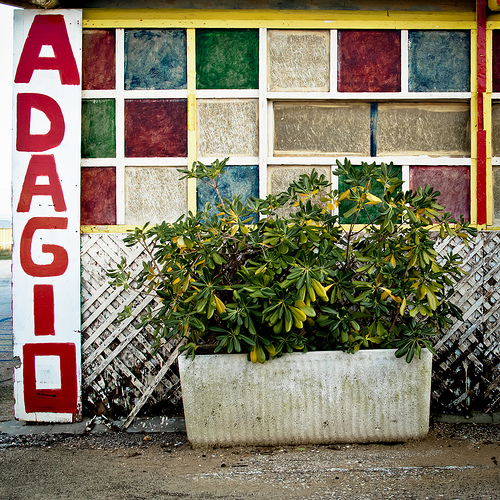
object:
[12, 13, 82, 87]
letter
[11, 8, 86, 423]
sign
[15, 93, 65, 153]
letter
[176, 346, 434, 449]
pot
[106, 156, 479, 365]
plant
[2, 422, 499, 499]
ground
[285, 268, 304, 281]
leaf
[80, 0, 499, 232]
wall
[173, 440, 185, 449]
rock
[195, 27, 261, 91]
tile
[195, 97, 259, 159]
tile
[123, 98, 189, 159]
tile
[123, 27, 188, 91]
tile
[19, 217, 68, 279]
letter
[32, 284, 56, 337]
letter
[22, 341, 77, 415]
letter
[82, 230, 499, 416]
trellis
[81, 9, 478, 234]
trim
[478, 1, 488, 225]
trim